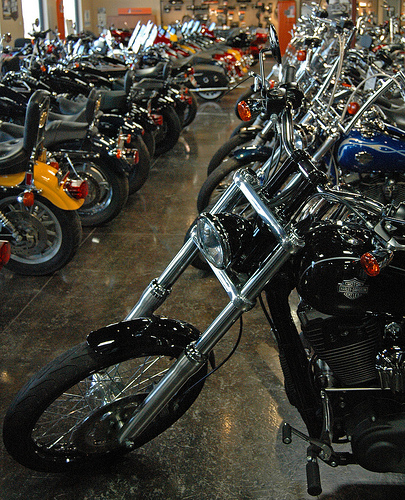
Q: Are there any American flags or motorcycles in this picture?
A: Yes, there is a motorcycle.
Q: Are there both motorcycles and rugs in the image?
A: No, there is a motorcycle but no rugs.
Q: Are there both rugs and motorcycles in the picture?
A: No, there is a motorcycle but no rugs.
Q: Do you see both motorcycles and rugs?
A: No, there is a motorcycle but no rugs.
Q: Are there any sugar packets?
A: No, there are no sugar packets.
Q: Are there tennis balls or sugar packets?
A: No, there are no sugar packets or tennis balls.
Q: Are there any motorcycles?
A: Yes, there are motorcycles.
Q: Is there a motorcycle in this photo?
A: Yes, there are motorcycles.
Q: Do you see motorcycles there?
A: Yes, there are motorcycles.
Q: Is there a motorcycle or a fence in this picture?
A: Yes, there are motorcycles.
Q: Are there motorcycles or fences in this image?
A: Yes, there are motorcycles.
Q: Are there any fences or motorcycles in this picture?
A: Yes, there are motorcycles.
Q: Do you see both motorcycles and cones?
A: No, there are motorcycles but no cones.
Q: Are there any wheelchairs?
A: No, there are no wheelchairs.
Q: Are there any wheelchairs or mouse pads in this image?
A: No, there are no wheelchairs or mouse pads.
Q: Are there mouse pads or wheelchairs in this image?
A: No, there are no wheelchairs or mouse pads.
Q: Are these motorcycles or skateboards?
A: These are motorcycles.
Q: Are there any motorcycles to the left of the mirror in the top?
A: Yes, there are motorcycles to the left of the mirror.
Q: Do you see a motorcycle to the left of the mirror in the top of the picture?
A: Yes, there are motorcycles to the left of the mirror.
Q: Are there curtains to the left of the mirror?
A: No, there are motorcycles to the left of the mirror.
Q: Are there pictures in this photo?
A: No, there are no pictures.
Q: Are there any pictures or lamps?
A: No, there are no pictures or lamps.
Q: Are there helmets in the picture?
A: No, there are no helmets.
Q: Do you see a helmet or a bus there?
A: No, there are no helmets or buses.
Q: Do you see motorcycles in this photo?
A: Yes, there is a motorcycle.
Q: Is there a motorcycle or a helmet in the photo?
A: Yes, there is a motorcycle.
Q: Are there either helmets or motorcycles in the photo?
A: Yes, there is a motorcycle.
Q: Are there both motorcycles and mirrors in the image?
A: Yes, there are both a motorcycle and a mirror.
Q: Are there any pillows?
A: No, there are no pillows.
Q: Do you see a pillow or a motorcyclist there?
A: No, there are no pillows or bikers.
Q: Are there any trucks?
A: No, there are no trucks.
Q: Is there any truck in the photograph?
A: No, there are no trucks.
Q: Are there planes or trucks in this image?
A: No, there are no trucks or planes.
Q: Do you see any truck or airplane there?
A: No, there are no trucks or airplanes.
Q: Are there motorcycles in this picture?
A: Yes, there is a motorcycle.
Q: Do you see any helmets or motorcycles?
A: Yes, there is a motorcycle.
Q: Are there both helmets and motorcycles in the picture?
A: No, there is a motorcycle but no helmets.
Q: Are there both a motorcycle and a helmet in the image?
A: No, there is a motorcycle but no helmets.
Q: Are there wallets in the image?
A: No, there are no wallets.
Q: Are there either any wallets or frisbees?
A: No, there are no wallets or frisbees.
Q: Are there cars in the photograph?
A: No, there are no cars.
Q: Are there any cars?
A: No, there are no cars.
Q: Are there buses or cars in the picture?
A: No, there are no cars or buses.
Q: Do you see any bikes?
A: Yes, there are bikes.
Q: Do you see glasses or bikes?
A: Yes, there are bikes.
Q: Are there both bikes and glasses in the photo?
A: No, there are bikes but no glasses.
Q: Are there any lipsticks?
A: No, there are no lipsticks.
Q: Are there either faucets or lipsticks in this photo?
A: No, there are no lipsticks or faucets.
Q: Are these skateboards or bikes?
A: These are bikes.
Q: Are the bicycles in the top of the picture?
A: Yes, the bicycles are in the top of the image.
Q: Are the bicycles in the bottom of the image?
A: No, the bicycles are in the top of the image.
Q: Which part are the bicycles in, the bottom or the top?
A: The bicycles are in the top of the image.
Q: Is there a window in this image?
A: Yes, there is a window.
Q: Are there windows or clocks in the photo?
A: Yes, there is a window.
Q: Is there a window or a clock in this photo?
A: Yes, there is a window.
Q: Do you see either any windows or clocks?
A: Yes, there is a window.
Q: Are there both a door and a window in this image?
A: Yes, there are both a window and a door.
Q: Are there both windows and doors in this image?
A: Yes, there are both a window and a door.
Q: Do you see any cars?
A: No, there are no cars.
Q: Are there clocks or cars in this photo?
A: No, there are no cars or clocks.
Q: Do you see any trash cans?
A: No, there are no trash cans.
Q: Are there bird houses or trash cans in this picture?
A: No, there are no trash cans or bird houses.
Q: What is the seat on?
A: The seat is on the motorbike.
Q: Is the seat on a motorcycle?
A: Yes, the seat is on a motorcycle.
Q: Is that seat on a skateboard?
A: No, the seat is on a motorcycle.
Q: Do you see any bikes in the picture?
A: Yes, there is a bike.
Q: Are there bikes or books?
A: Yes, there is a bike.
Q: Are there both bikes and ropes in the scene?
A: No, there is a bike but no ropes.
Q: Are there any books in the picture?
A: No, there are no books.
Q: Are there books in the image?
A: No, there are no books.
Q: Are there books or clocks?
A: No, there are no books or clocks.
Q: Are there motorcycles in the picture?
A: Yes, there is a motorcycle.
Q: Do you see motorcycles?
A: Yes, there is a motorcycle.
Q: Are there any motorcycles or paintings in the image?
A: Yes, there is a motorcycle.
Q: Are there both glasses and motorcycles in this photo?
A: No, there is a motorcycle but no glasses.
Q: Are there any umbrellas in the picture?
A: No, there are no umbrellas.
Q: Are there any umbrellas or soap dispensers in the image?
A: No, there are no umbrellas or soap dispensers.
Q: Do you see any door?
A: Yes, there is a door.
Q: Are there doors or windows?
A: Yes, there is a door.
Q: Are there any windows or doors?
A: Yes, there is a door.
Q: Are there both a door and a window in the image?
A: Yes, there are both a door and a window.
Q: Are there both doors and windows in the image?
A: Yes, there are both a door and a window.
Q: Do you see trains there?
A: No, there are no trains.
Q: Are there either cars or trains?
A: No, there are no trains or cars.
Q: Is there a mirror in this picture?
A: Yes, there is a mirror.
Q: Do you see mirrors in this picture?
A: Yes, there is a mirror.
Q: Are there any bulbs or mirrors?
A: Yes, there is a mirror.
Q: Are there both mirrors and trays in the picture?
A: No, there is a mirror but no trays.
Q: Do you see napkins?
A: No, there are no napkins.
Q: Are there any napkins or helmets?
A: No, there are no napkins or helmets.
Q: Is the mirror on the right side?
A: Yes, the mirror is on the right of the image.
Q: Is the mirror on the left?
A: No, the mirror is on the right of the image.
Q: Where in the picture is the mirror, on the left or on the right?
A: The mirror is on the right of the image.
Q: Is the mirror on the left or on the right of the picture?
A: The mirror is on the right of the image.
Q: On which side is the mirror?
A: The mirror is on the right of the image.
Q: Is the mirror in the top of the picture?
A: Yes, the mirror is in the top of the image.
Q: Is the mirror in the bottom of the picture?
A: No, the mirror is in the top of the image.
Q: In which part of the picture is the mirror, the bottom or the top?
A: The mirror is in the top of the image.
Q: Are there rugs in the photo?
A: No, there are no rugs.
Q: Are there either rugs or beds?
A: No, there are no rugs or beds.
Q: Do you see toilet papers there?
A: No, there are no toilet papers.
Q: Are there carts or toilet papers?
A: No, there are no toilet papers or carts.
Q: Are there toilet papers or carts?
A: No, there are no toilet papers or carts.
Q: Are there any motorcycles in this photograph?
A: Yes, there is a motorcycle.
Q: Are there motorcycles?
A: Yes, there is a motorcycle.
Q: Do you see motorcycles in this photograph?
A: Yes, there is a motorcycle.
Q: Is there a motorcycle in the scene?
A: Yes, there is a motorcycle.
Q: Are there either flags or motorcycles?
A: Yes, there is a motorcycle.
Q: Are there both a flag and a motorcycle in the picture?
A: No, there is a motorcycle but no flags.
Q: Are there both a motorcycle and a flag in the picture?
A: No, there is a motorcycle but no flags.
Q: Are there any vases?
A: No, there are no vases.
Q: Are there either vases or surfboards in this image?
A: No, there are no vases or surfboards.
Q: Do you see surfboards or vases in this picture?
A: No, there are no vases or surfboards.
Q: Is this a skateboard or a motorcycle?
A: This is a motorcycle.